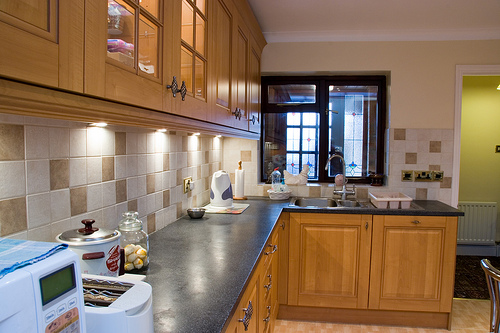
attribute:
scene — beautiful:
[3, 3, 495, 333]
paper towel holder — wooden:
[229, 158, 250, 200]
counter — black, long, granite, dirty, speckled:
[174, 222, 225, 329]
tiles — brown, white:
[395, 131, 452, 195]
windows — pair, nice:
[264, 77, 390, 186]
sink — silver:
[304, 172, 370, 210]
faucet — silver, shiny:
[336, 176, 358, 204]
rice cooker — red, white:
[66, 219, 127, 278]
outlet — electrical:
[182, 181, 196, 197]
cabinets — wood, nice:
[1, 10, 263, 141]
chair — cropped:
[470, 254, 496, 332]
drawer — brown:
[260, 219, 288, 273]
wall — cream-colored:
[400, 56, 444, 126]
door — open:
[454, 69, 499, 264]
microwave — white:
[1, 237, 92, 331]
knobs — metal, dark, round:
[166, 77, 189, 101]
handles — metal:
[237, 302, 263, 325]